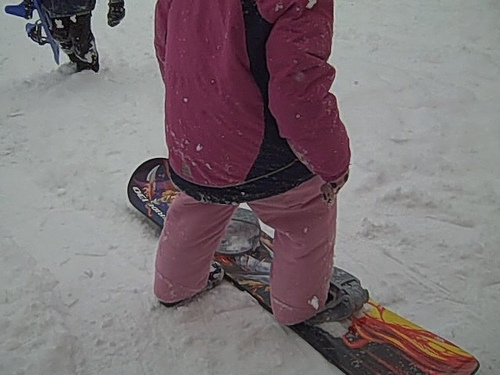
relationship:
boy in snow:
[153, 0, 351, 326] [377, 100, 479, 278]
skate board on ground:
[126, 157, 480, 375] [19, 80, 463, 373]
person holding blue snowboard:
[1, 0, 126, 73] [25, 0, 60, 65]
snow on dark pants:
[56, 8, 99, 68] [36, 8, 108, 75]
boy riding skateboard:
[153, 0, 351, 326] [307, 299, 458, 374]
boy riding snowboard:
[147, 1, 353, 328] [125, 151, 479, 372]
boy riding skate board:
[147, 1, 353, 328] [123, 152, 481, 372]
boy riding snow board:
[147, 1, 353, 328] [127, 157, 479, 373]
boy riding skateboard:
[147, 1, 353, 328] [137, 140, 458, 374]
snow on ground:
[363, 67, 480, 190] [7, 8, 487, 367]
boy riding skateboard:
[147, 1, 353, 328] [124, 152, 479, 374]